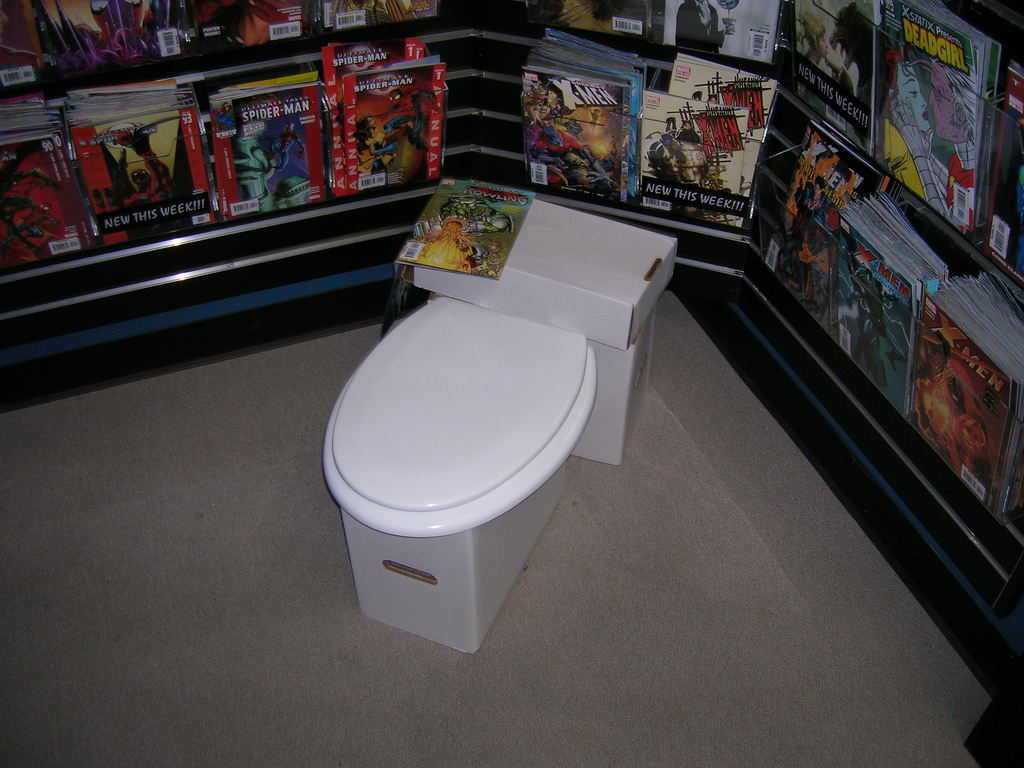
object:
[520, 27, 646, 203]
comic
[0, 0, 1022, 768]
shelf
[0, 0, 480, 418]
shelf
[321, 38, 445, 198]
comic